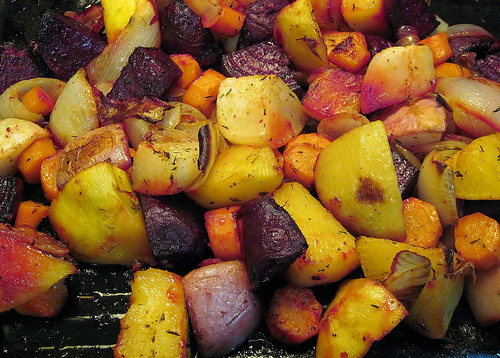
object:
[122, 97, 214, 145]
vegetables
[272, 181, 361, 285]
potato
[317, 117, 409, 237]
lemon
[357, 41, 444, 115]
fruit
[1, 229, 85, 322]
fruit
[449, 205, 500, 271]
fruit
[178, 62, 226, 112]
fruit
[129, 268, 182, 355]
food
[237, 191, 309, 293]
food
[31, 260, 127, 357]
grill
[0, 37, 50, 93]
onions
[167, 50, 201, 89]
carrot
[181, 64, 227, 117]
carrot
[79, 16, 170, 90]
onion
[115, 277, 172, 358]
surface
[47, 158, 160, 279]
food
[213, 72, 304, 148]
potato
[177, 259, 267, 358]
onion